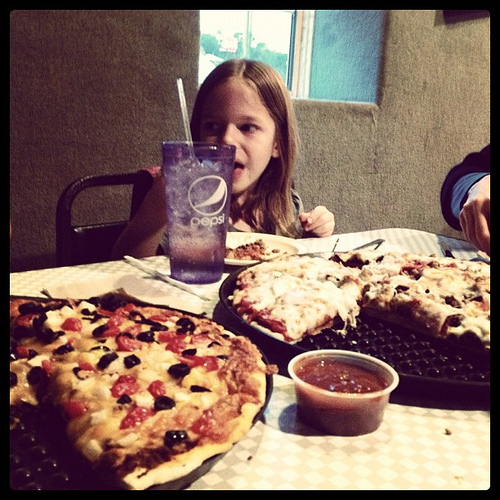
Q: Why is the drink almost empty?
A: The girl drank all of it.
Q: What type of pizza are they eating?
A: Supreme.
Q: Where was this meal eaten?
A: Italian restaurant.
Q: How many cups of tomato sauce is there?
A: One.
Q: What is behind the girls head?
A: A window.